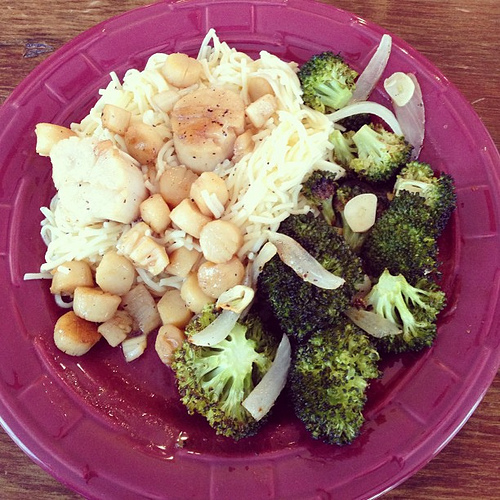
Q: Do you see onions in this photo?
A: Yes, there is an onion.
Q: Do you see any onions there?
A: Yes, there is an onion.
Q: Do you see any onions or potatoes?
A: Yes, there is an onion.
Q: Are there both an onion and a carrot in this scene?
A: No, there is an onion but no carrots.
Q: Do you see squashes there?
A: No, there are no squashes.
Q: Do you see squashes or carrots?
A: No, there are no squashes or carrots.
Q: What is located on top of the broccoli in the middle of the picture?
A: The onion is on top of the broccoli.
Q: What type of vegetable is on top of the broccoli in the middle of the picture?
A: The vegetable is an onion.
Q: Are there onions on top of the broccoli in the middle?
A: Yes, there is an onion on top of the broccoli.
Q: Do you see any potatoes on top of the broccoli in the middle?
A: No, there is an onion on top of the broccoli.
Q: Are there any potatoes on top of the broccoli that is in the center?
A: No, there is an onion on top of the broccoli.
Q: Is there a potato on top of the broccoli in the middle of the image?
A: No, there is an onion on top of the broccoli.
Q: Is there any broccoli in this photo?
A: Yes, there is broccoli.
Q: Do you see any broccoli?
A: Yes, there is broccoli.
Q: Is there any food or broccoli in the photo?
A: Yes, there is broccoli.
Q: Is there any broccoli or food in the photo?
A: Yes, there is broccoli.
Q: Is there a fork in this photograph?
A: No, there are no forks.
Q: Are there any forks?
A: No, there are no forks.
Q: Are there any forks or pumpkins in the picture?
A: No, there are no forks or pumpkins.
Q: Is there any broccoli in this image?
A: Yes, there is broccoli.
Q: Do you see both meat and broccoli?
A: Yes, there are both broccoli and meat.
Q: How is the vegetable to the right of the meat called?
A: The vegetable is broccoli.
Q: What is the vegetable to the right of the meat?
A: The vegetable is broccoli.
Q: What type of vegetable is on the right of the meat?
A: The vegetable is broccoli.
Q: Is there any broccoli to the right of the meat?
A: Yes, there is broccoli to the right of the meat.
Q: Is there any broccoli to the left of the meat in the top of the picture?
A: No, the broccoli is to the right of the meat.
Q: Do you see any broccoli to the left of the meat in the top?
A: No, the broccoli is to the right of the meat.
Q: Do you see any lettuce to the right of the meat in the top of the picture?
A: No, there is broccoli to the right of the meat.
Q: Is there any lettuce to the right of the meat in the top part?
A: No, there is broccoli to the right of the meat.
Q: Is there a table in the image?
A: Yes, there is a table.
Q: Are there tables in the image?
A: Yes, there is a table.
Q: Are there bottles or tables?
A: Yes, there is a table.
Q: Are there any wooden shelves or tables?
A: Yes, there is a wood table.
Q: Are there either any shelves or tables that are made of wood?
A: Yes, the table is made of wood.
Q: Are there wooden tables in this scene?
A: Yes, there is a wood table.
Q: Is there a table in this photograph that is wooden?
A: Yes, there is a table that is wooden.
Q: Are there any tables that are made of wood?
A: Yes, there is a table that is made of wood.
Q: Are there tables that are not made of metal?
A: Yes, there is a table that is made of wood.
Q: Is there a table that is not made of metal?
A: Yes, there is a table that is made of wood.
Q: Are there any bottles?
A: No, there are no bottles.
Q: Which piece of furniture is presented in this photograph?
A: The piece of furniture is a table.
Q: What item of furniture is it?
A: The piece of furniture is a table.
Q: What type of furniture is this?
A: This is a table.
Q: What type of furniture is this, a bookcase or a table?
A: This is a table.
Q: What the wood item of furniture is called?
A: The piece of furniture is a table.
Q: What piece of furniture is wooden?
A: The piece of furniture is a table.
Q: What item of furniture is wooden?
A: The piece of furniture is a table.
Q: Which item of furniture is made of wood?
A: The piece of furniture is a table.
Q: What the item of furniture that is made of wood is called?
A: The piece of furniture is a table.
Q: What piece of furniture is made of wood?
A: The piece of furniture is a table.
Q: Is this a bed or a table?
A: This is a table.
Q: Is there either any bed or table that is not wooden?
A: No, there is a table but it is wooden.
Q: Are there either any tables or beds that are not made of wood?
A: No, there is a table but it is made of wood.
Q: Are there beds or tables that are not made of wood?
A: No, there is a table but it is made of wood.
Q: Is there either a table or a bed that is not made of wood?
A: No, there is a table but it is made of wood.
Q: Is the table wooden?
A: Yes, the table is wooden.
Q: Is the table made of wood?
A: Yes, the table is made of wood.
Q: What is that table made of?
A: The table is made of wood.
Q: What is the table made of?
A: The table is made of wood.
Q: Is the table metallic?
A: No, the table is wooden.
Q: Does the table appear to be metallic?
A: No, the table is wooden.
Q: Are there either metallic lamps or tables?
A: No, there is a table but it is wooden.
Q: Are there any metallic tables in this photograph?
A: No, there is a table but it is wooden.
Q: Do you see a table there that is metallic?
A: No, there is a table but it is wooden.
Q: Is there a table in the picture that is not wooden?
A: No, there is a table but it is wooden.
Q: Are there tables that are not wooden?
A: No, there is a table but it is wooden.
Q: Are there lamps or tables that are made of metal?
A: No, there is a table but it is made of wood.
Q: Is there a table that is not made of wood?
A: No, there is a table but it is made of wood.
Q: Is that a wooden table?
A: Yes, that is a wooden table.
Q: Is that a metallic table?
A: No, that is a wooden table.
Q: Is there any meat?
A: Yes, there is meat.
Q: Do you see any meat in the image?
A: Yes, there is meat.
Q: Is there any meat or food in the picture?
A: Yes, there is meat.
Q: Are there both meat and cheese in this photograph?
A: No, there is meat but no cheese.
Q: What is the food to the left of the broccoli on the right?
A: The food is meat.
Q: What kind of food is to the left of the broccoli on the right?
A: The food is meat.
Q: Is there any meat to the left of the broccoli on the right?
A: Yes, there is meat to the left of the broccoli.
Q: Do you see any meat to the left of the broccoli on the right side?
A: Yes, there is meat to the left of the broccoli.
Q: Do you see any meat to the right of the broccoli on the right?
A: No, the meat is to the left of the broccoli.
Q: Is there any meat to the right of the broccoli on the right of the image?
A: No, the meat is to the left of the broccoli.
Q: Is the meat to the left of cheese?
A: No, the meat is to the left of the broccoli.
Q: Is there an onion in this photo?
A: Yes, there is an onion.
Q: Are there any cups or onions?
A: Yes, there is an onion.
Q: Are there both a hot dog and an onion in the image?
A: No, there is an onion but no hot dogs.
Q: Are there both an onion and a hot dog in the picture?
A: No, there is an onion but no hot dogs.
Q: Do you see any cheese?
A: No, there is no cheese.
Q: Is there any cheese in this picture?
A: No, there is no cheese.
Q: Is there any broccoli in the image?
A: Yes, there is broccoli.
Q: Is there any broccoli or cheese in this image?
A: Yes, there is broccoli.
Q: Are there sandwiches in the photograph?
A: No, there are no sandwiches.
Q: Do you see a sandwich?
A: No, there are no sandwiches.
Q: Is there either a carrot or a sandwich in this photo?
A: No, there are no sandwiches or carrots.